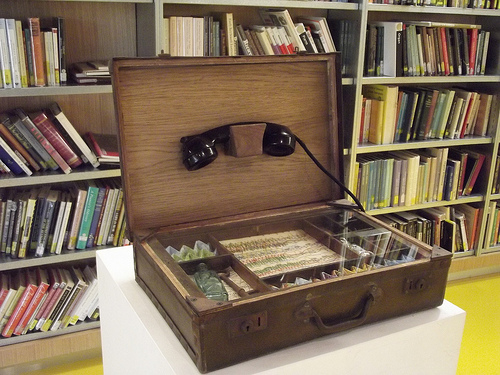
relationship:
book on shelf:
[369, 79, 397, 150] [341, 7, 498, 289]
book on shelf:
[394, 89, 409, 144] [341, 7, 498, 289]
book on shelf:
[407, 89, 421, 146] [341, 7, 498, 289]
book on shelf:
[417, 82, 439, 143] [341, 7, 498, 289]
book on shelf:
[433, 83, 458, 146] [341, 7, 498, 289]